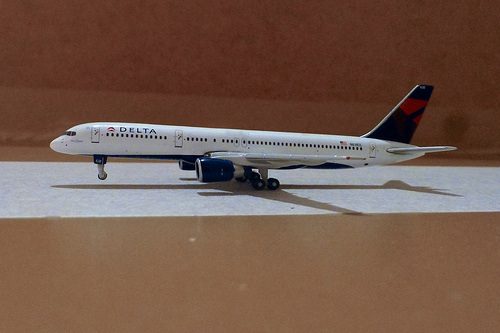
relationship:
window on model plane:
[104, 132, 111, 136] [54, 86, 451, 195]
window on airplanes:
[109, 123, 141, 143] [49, 84, 457, 192]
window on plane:
[182, 134, 192, 144] [44, 78, 462, 198]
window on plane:
[201, 132, 216, 153] [44, 78, 462, 198]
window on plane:
[220, 137, 227, 145] [44, 78, 462, 198]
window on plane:
[201, 130, 231, 147] [44, 78, 462, 198]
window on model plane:
[299, 143, 309, 150] [49, 83, 459, 187]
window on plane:
[273, 139, 288, 151] [15, 47, 498, 212]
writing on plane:
[111, 123, 162, 145] [44, 78, 462, 198]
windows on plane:
[100, 129, 367, 153] [15, 67, 499, 205]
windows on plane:
[63, 127, 84, 147] [44, 78, 462, 198]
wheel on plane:
[252, 178, 267, 192] [50, 82, 455, 187]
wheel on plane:
[266, 177, 281, 191] [50, 82, 455, 187]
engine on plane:
[185, 151, 241, 186] [57, 87, 479, 239]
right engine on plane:
[175, 156, 195, 173] [50, 82, 455, 187]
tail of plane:
[362, 82, 437, 145] [50, 82, 455, 187]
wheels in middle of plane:
[242, 169, 297, 191] [50, 82, 455, 187]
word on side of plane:
[121, 124, 158, 135] [50, 82, 455, 187]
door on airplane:
[172, 128, 185, 151] [46, 83, 458, 193]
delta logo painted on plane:
[106, 124, 158, 134] [50, 82, 455, 187]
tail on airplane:
[358, 83, 434, 144] [36, 77, 470, 206]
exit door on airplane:
[367, 141, 376, 161] [46, 83, 458, 193]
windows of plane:
[63, 126, 76, 137] [44, 78, 462, 198]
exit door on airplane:
[82, 121, 106, 150] [46, 83, 458, 193]